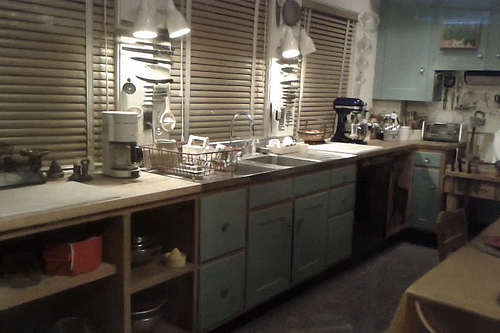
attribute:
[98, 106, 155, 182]
coffee maker — white, black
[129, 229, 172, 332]
bowls — metallic, silver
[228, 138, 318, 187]
sink — stainless steel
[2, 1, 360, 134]
blinds — down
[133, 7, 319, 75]
light — one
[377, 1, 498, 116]
cupboard — blue, wooden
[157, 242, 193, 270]
fruit juicer — pointed, white, yellow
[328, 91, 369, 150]
mixer — black, silver, dark blue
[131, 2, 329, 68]
lights — white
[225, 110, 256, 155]
faucet — stainless steel, curved, silver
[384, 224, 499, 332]
tablecloth — yellow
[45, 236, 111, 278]
pot — red